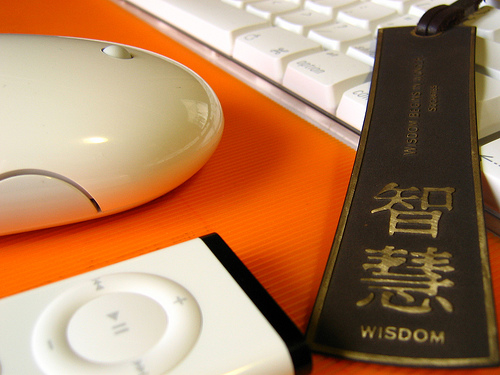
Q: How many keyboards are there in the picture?
A: One.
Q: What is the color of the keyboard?
A: White.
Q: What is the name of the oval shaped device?
A: A mouse.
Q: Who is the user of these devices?
A: A chinese person.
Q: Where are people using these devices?
A: In China.